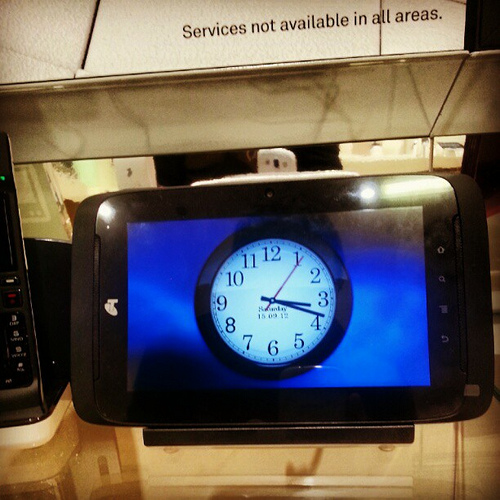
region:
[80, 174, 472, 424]
this is a cell phone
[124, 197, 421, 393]
the cell phone is on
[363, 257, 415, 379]
the light is blue in color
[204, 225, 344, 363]
this is a clock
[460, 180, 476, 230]
the cell phone is black in color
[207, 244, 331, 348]
the time is three eighteen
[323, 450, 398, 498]
this is the table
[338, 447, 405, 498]
the table is glass like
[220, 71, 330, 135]
this is the stand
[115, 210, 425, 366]
the screen is clear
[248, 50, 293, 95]
edge of a ceiling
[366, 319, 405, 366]
part of a screen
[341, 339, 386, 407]
par of a screen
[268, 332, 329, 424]
part of a clock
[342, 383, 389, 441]
edge of a screen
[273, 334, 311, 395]
part of a clock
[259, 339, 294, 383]
part of a clock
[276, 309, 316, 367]
part of a clock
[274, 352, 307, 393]
edge fo a clock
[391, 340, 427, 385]
part of a screen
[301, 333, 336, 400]
edge of a clock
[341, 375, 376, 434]
part of a screen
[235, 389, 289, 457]
edge of a screen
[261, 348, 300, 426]
part of a clock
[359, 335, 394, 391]
part of a screen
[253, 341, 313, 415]
edge of a clock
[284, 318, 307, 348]
part of a clockj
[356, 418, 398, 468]
part of a handle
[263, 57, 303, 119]
part of a shade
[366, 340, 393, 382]
part of a screen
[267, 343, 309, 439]
part of a scren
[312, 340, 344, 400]
part of a glass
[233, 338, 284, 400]
edge of a clock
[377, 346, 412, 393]
part of a glass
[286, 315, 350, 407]
part of a clock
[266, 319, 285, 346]
part of a number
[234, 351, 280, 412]
edge of a board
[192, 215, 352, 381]
round analog clock reading 3:18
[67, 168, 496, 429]
rectangular android operated tablet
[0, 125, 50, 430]
big black portable telephone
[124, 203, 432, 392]
bright blue screen surrounding clock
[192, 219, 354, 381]
black round frame around clock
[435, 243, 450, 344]
control buttons on right side of tablet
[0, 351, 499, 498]
clear tabletop that the tablet and phone are on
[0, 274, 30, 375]
dial keypad on portable phone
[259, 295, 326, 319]
minute hand on clock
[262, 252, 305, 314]
second hand on the clock